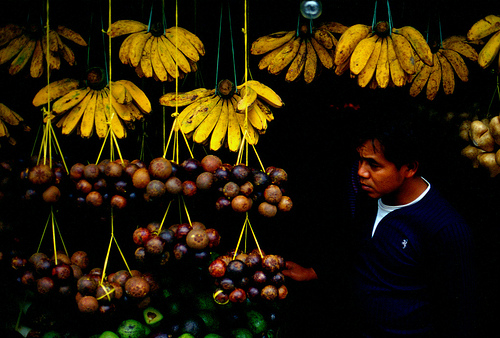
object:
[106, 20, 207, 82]
bananas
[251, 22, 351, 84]
bananas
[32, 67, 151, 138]
bananas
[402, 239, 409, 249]
logo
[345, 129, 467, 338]
man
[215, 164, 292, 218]
fruit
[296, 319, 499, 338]
ground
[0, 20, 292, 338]
different fruit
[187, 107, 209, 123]
discoloration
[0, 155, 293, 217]
fruit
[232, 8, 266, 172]
string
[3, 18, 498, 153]
plantains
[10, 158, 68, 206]
round fruit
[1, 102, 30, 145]
bunch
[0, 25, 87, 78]
bunch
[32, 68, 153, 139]
bunch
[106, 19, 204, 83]
bunch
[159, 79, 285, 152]
bunch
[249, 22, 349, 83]
bunch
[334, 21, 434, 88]
bunch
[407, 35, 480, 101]
bunch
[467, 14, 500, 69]
bunch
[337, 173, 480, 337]
sweater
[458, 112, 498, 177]
potatoes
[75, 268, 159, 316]
fruits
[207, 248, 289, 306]
fruit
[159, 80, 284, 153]
banana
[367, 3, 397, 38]
string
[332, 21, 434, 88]
bananas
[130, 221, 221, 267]
fruit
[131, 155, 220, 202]
fruit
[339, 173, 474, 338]
shirt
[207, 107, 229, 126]
skin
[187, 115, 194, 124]
blemish